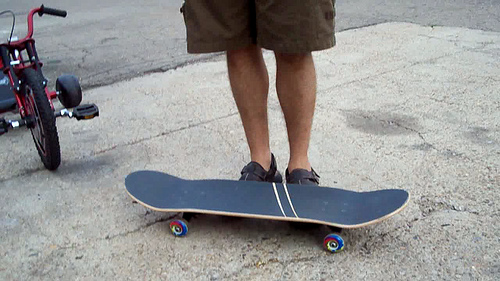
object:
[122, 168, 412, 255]
skateboard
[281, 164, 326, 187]
shoe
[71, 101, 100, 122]
pedal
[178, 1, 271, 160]
leg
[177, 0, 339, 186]
man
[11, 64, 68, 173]
tire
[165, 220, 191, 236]
wheel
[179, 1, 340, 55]
short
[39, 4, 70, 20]
handle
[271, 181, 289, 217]
strip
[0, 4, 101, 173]
bike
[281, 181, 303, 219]
line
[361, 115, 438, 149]
crack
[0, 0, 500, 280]
pavement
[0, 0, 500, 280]
ground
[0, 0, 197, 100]
asphalt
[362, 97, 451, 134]
concrete